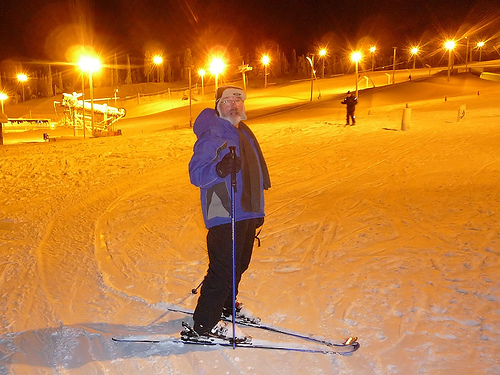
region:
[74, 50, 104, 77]
bright yellow colored light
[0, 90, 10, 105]
bright yellow colored light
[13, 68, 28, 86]
bright yellow colored light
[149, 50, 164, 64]
bright yellow colored light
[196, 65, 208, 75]
bright yellow colored light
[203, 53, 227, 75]
bright yellow colored light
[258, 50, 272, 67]
bright yellow colored light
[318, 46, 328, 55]
bright yellow colored light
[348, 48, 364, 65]
bright yellow colored light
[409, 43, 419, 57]
bright yellow colored light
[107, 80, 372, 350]
man wearing skis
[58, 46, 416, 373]
man wearing a blue jacket and black pants wearing skis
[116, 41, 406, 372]
man wearing a blue jacket and black pants wearing skiing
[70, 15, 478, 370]
man with grey beard skiing at night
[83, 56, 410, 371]
man with grey beard wearing glasses skiing at night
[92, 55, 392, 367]
man with grey beard wearing glasses skiing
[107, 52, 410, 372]
man with grey beard holding a ski pole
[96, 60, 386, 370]
man holding a ski pole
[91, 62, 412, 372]
skier standing in the snow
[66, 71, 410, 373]
male skier standing in the snow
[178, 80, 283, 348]
Man wearing a blue jacket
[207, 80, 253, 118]
Cap on the man's head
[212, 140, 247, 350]
Ski pole in the man's hand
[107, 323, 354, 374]
Ski on the man's foot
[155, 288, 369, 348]
Ski on the man's foot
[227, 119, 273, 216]
Scarf around the man's neck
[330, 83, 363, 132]
Man in the background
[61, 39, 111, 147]
Street light in the backgrouund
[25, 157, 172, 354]
Track marks on the snow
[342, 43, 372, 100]
Street light in the background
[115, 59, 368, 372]
man blue jacket on skis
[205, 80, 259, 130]
brown fur lined hat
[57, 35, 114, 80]
bright lights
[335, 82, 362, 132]
person wearing black snow suit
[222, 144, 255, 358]
blue shaft ski pole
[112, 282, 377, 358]
snow covered white skis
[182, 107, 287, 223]
blue ski jacket with black and gray pattern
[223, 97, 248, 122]
bearded man wearing glasses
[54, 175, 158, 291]
packed snow with ski marks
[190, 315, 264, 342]
black ski boot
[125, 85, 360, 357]
a man is wearing skis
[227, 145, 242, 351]
ski pole is in a man's hand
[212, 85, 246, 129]
hat and glasses on man's head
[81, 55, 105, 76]
a light is far away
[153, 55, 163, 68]
a light is far away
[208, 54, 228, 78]
a light is far away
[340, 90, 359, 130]
a person is walking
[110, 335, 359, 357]
a ski is on a man's foot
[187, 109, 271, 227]
a blue and black jacket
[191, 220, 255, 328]
black pants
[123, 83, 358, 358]
the man is skiing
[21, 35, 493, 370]
a scene during the night time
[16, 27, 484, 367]
a scene in the slopes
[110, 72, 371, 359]
a skier posing for the camera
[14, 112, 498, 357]
some snow on the ground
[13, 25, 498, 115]
a couple of rows of lights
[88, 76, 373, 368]
a person in the background in black attire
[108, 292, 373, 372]
a pair of skies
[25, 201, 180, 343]
a trail of tracks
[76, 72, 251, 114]
a fence in the background